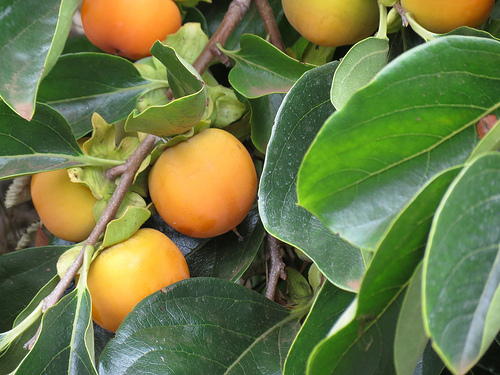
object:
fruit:
[30, 170, 98, 243]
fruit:
[147, 128, 259, 238]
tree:
[1, 1, 500, 374]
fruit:
[281, 0, 381, 48]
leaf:
[295, 34, 500, 251]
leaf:
[421, 152, 499, 374]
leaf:
[98, 275, 303, 375]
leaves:
[2, 244, 95, 374]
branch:
[86, 0, 252, 247]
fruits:
[56, 227, 191, 331]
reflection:
[71, 306, 83, 374]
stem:
[82, 154, 128, 167]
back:
[437, 219, 457, 266]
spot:
[475, 114, 497, 138]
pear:
[400, 0, 494, 34]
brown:
[266, 17, 277, 30]